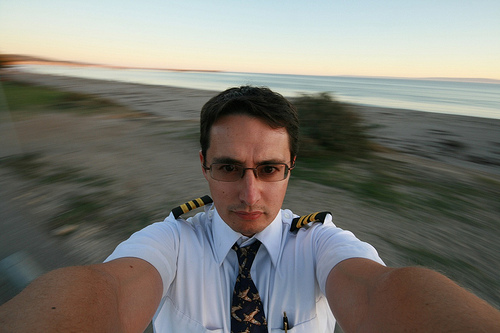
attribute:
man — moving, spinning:
[0, 86, 500, 332]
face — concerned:
[204, 112, 292, 235]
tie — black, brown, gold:
[232, 239, 269, 332]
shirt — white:
[102, 194, 387, 333]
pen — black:
[282, 311, 290, 332]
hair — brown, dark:
[200, 86, 301, 173]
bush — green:
[289, 92, 387, 166]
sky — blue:
[2, 1, 500, 79]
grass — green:
[0, 81, 63, 110]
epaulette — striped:
[290, 211, 332, 231]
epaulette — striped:
[170, 194, 214, 219]